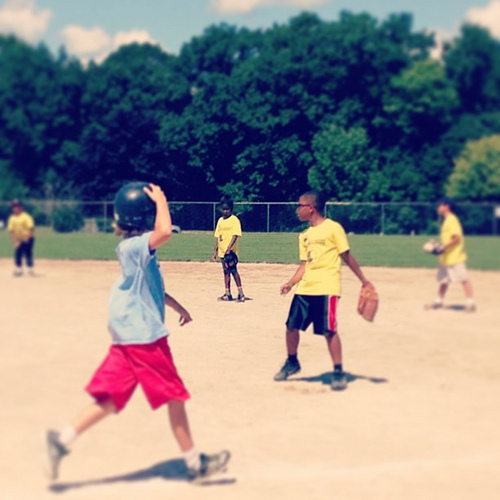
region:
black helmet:
[114, 155, 206, 260]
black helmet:
[97, 127, 198, 234]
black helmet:
[90, 98, 214, 325]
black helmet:
[108, 160, 166, 257]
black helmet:
[89, 143, 172, 280]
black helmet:
[123, 192, 187, 276]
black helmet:
[126, 162, 171, 224]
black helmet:
[110, 177, 223, 297]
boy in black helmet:
[82, 161, 203, 248]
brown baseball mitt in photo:
[352, 278, 399, 346]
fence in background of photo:
[20, 175, 464, 237]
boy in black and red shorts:
[280, 287, 360, 344]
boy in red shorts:
[77, 321, 225, 412]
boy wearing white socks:
[44, 414, 241, 469]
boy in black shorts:
[190, 232, 235, 286]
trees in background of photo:
[31, 61, 431, 216]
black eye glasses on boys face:
[284, 195, 325, 216]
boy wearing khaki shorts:
[402, 251, 480, 303]